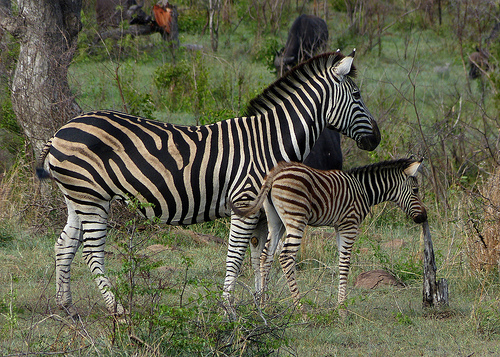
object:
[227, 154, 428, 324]
zebra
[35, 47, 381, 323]
zebra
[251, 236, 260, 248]
patch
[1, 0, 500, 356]
area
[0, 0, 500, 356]
branches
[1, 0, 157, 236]
tree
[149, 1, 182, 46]
trunk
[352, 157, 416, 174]
mane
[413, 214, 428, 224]
mouth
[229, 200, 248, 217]
hair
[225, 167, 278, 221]
tail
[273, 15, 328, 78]
buffalo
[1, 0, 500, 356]
forrest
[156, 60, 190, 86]
greenery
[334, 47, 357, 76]
ear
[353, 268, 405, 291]
rock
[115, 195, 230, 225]
stomach